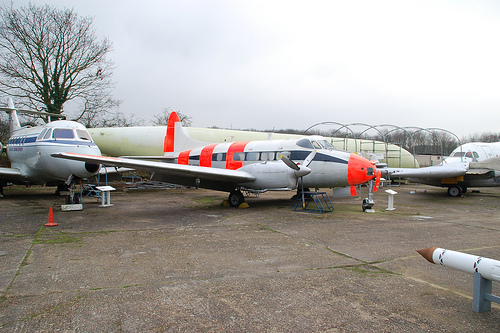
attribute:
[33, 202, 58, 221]
cone — orange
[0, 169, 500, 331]
ground — concrete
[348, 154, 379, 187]
nose — orange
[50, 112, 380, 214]
plane — orange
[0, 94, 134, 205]
airplane — white, blue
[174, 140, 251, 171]
stripes — orange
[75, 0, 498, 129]
sky — cloudy, grey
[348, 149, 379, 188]
paint — orange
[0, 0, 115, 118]
bare tree — tall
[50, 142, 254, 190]
wing — plane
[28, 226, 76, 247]
grass — growing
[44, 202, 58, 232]
cone — orange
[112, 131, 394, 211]
plane — small, passenger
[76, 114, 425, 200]
plane — big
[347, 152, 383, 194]
nose — bright, orange, painted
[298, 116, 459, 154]
object — metal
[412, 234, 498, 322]
object — white, missile shaped